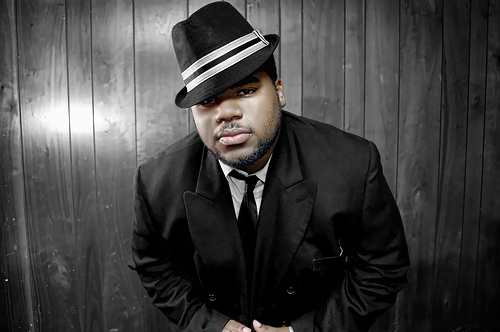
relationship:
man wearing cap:
[128, 1, 415, 328] [171, 1, 281, 109]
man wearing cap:
[128, 1, 415, 328] [161, 24, 285, 76]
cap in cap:
[171, 1, 281, 109] [165, 1, 281, 114]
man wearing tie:
[128, 1, 415, 328] [231, 166, 266, 266]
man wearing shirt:
[128, 1, 412, 332] [213, 157, 271, 222]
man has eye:
[128, 1, 415, 328] [239, 83, 261, 95]